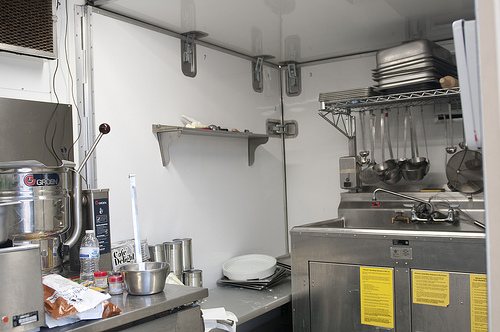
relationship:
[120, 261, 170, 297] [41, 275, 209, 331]
mixing bowl on top of counter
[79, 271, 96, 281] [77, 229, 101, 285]
water inside of bottle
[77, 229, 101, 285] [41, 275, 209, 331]
bottle on top of counter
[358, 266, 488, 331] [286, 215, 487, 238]
signs in front of sink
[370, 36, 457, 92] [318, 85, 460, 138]
pans on top of shelf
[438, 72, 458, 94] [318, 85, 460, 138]
rolling pin on top of shelf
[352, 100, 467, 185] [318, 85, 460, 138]
ladles hanging from shelf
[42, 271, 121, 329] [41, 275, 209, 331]
bags on top of counter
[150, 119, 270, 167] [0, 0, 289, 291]
shelf mounted on wall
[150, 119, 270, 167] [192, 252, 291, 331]
shelf above counter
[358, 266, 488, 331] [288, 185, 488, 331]
signs on front of equipment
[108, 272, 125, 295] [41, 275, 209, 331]
spice bottle on top of counter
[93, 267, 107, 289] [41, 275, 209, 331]
spice bottle on top of counter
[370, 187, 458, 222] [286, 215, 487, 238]
faucet on back of sink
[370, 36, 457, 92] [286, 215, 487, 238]
pans above sink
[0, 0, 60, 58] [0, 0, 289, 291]
exhaust vent inside of wall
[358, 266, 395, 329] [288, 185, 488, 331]
signs on front of equipment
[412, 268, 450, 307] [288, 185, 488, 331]
sign on front of equipment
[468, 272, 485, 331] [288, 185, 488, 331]
sign on front of equipment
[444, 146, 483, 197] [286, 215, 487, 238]
strainer hanging above sink